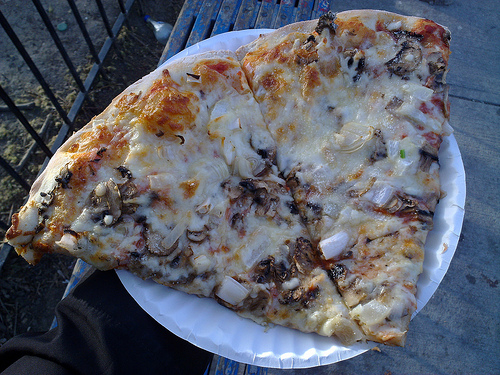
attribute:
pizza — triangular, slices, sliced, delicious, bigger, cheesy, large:
[4, 9, 450, 350]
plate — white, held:
[116, 28, 467, 371]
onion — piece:
[216, 274, 253, 309]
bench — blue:
[49, 2, 338, 373]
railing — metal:
[1, 1, 160, 274]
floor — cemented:
[332, 3, 498, 373]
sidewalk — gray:
[271, 3, 499, 374]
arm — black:
[1, 265, 214, 373]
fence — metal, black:
[1, 1, 166, 271]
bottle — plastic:
[144, 12, 175, 45]